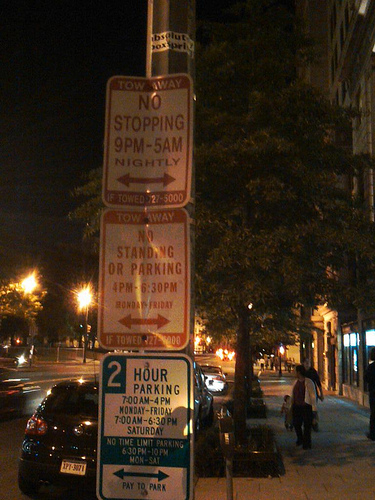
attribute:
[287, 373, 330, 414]
jacket — white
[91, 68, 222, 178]
sign — top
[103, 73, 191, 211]
sign — red, white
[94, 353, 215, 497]
sign — white, green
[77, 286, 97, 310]
light flare — bright